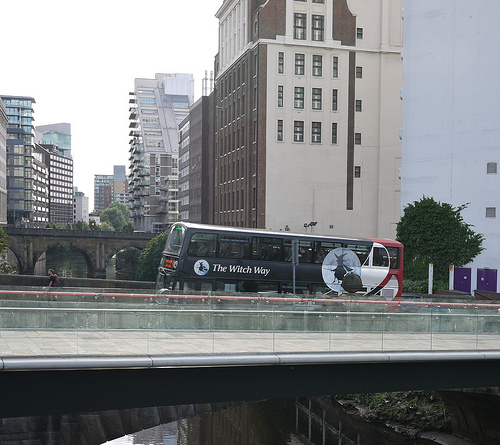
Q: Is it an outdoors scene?
A: Yes, it is outdoors.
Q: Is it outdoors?
A: Yes, it is outdoors.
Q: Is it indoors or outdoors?
A: It is outdoors.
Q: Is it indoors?
A: No, it is outdoors.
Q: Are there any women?
A: No, there are no women.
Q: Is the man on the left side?
A: Yes, the man is on the left of the image.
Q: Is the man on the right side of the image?
A: No, the man is on the left of the image.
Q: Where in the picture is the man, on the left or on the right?
A: The man is on the left of the image.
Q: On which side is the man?
A: The man is on the left of the image.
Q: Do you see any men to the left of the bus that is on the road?
A: Yes, there is a man to the left of the bus.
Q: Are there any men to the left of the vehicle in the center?
A: Yes, there is a man to the left of the bus.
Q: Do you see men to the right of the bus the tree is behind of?
A: No, the man is to the left of the bus.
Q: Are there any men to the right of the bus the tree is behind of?
A: No, the man is to the left of the bus.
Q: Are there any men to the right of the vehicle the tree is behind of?
A: No, the man is to the left of the bus.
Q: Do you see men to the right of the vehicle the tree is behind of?
A: No, the man is to the left of the bus.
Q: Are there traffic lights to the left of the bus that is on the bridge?
A: No, there is a man to the left of the bus.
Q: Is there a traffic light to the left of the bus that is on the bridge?
A: No, there is a man to the left of the bus.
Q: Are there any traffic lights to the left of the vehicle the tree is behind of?
A: No, there is a man to the left of the bus.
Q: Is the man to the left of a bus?
A: Yes, the man is to the left of a bus.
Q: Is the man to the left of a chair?
A: No, the man is to the left of a bus.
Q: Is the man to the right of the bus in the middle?
A: No, the man is to the left of the bus.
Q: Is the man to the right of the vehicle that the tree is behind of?
A: No, the man is to the left of the bus.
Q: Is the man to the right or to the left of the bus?
A: The man is to the left of the bus.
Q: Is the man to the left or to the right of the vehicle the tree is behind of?
A: The man is to the left of the bus.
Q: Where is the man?
A: The man is on the street.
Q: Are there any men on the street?
A: Yes, there is a man on the street.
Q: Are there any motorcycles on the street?
A: No, there is a man on the street.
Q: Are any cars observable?
A: No, there are no cars.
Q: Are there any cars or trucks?
A: No, there are no cars or trucks.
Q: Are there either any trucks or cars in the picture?
A: No, there are no cars or trucks.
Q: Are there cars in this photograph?
A: No, there are no cars.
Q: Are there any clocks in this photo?
A: No, there are no clocks.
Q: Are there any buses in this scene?
A: Yes, there is a bus.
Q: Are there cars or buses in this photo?
A: Yes, there is a bus.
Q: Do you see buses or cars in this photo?
A: Yes, there is a bus.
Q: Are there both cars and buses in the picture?
A: No, there is a bus but no cars.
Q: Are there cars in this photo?
A: No, there are no cars.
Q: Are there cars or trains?
A: No, there are no cars or trains.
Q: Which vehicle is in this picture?
A: The vehicle is a bus.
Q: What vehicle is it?
A: The vehicle is a bus.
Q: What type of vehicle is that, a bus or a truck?
A: This is a bus.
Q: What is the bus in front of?
A: The bus is in front of the tree.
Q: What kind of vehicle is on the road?
A: The vehicle is a bus.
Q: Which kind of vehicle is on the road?
A: The vehicle is a bus.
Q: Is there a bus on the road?
A: Yes, there is a bus on the road.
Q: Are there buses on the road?
A: Yes, there is a bus on the road.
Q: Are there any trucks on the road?
A: No, there is a bus on the road.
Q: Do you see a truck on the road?
A: No, there is a bus on the road.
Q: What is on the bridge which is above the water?
A: The bus is on the bridge.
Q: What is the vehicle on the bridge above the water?
A: The vehicle is a bus.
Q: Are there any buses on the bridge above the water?
A: Yes, there is a bus on the bridge.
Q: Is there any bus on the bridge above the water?
A: Yes, there is a bus on the bridge.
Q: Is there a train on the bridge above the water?
A: No, there is a bus on the bridge.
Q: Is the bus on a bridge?
A: Yes, the bus is on a bridge.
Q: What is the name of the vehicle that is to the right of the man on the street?
A: The vehicle is a bus.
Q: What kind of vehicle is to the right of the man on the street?
A: The vehicle is a bus.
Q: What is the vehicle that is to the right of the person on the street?
A: The vehicle is a bus.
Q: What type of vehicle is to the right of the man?
A: The vehicle is a bus.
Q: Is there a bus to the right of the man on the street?
A: Yes, there is a bus to the right of the man.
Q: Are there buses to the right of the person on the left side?
A: Yes, there is a bus to the right of the man.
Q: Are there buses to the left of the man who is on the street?
A: No, the bus is to the right of the man.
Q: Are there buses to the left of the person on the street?
A: No, the bus is to the right of the man.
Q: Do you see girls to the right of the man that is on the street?
A: No, there is a bus to the right of the man.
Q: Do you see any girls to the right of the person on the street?
A: No, there is a bus to the right of the man.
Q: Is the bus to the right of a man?
A: Yes, the bus is to the right of a man.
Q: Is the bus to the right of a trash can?
A: No, the bus is to the right of a man.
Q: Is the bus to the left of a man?
A: No, the bus is to the right of a man.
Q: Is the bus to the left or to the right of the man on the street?
A: The bus is to the right of the man.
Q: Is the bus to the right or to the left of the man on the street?
A: The bus is to the right of the man.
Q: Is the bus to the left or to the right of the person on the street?
A: The bus is to the right of the man.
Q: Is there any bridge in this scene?
A: Yes, there is a bridge.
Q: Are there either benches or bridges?
A: Yes, there is a bridge.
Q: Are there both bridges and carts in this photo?
A: No, there is a bridge but no carts.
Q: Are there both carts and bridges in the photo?
A: No, there is a bridge but no carts.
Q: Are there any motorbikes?
A: No, there are no motorbikes.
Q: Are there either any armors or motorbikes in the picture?
A: No, there are no motorbikes or armors.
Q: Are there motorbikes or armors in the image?
A: No, there are no motorbikes or armors.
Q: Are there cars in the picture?
A: No, there are no cars.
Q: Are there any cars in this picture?
A: No, there are no cars.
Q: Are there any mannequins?
A: No, there are no mannequins.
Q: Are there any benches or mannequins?
A: No, there are no mannequins or benches.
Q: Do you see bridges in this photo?
A: Yes, there is a bridge.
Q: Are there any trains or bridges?
A: Yes, there is a bridge.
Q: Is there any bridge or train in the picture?
A: Yes, there is a bridge.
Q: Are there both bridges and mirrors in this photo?
A: No, there is a bridge but no mirrors.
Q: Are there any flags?
A: No, there are no flags.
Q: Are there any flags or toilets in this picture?
A: No, there are no flags or toilets.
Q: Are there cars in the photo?
A: No, there are no cars.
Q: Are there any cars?
A: No, there are no cars.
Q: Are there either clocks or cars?
A: No, there are no cars or clocks.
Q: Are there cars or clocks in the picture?
A: No, there are no cars or clocks.